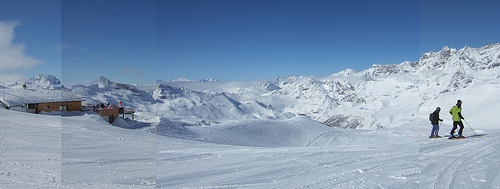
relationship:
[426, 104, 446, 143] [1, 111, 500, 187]
person on snow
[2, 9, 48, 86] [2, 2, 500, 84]
cloud in sky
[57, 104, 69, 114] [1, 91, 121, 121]
window open building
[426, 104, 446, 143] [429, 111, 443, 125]
person with arms down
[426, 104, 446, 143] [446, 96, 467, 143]
person behind another person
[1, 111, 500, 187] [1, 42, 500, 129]
snow on mountains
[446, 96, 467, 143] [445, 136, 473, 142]
person on skis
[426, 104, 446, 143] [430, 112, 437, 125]
person wears a backpack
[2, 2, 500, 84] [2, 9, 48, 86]
sky has one cloud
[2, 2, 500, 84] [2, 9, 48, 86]
sky has a lone cloud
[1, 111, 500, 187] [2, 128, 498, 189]
snow covers ground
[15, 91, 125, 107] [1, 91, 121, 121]
roof on a building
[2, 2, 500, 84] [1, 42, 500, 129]
sky above mountains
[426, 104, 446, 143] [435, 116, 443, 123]
person shows right hand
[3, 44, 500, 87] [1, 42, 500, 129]
ridge of mountains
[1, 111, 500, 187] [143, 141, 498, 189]
snow with tracks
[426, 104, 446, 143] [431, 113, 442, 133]
person wearing a jacket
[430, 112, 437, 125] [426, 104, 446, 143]
backpack on a person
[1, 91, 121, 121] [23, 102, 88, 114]
building from one side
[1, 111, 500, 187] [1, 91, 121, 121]
snow by building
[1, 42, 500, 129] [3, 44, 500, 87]
mountains form a ridge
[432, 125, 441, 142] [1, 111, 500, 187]
pants for snow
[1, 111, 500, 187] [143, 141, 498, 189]
snow has tracks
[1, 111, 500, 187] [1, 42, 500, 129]
snow covering mountains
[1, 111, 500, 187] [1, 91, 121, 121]
snow covers a building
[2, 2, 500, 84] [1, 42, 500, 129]
sky over mountains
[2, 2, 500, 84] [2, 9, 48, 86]
sky with a cloud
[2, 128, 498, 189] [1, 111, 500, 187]
ground covered in snow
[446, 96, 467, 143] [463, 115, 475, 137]
person with a ski pole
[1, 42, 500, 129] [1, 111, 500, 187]
mountains under snow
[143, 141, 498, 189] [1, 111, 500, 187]
tracks in snow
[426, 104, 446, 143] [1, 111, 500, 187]
person standing in snow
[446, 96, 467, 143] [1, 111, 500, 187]
person standing in snow